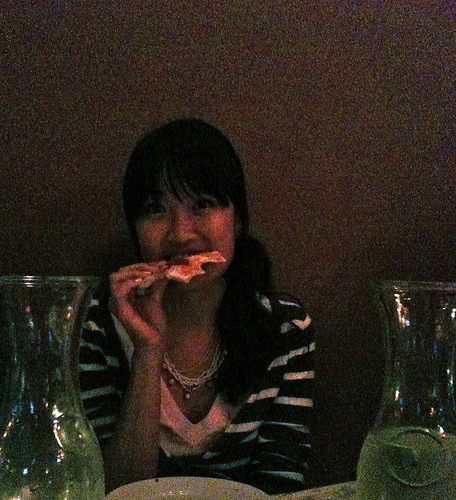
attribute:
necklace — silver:
[152, 346, 231, 402]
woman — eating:
[82, 108, 339, 496]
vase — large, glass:
[2, 261, 117, 498]